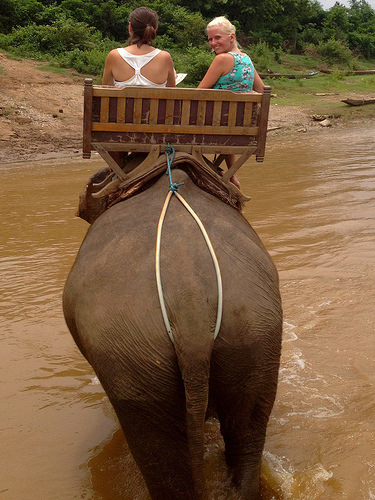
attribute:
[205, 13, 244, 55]
hair — blonde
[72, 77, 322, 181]
bench — brown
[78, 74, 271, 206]
bench — wooden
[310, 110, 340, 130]
rocks — small 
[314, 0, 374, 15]
sky — white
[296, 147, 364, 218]
water — brown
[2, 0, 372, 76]
trees — green, in background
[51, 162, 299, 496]
elephant — gray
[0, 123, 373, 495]
water — brown , Muddy , body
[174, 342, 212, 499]
tail — gray, scaly, hanging